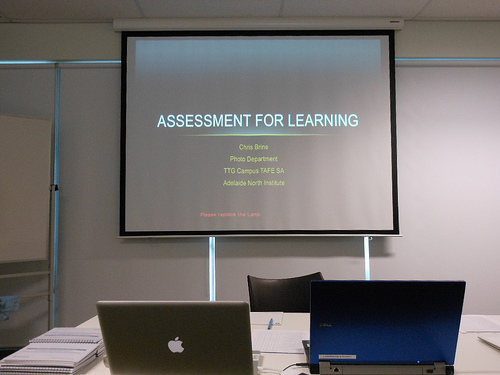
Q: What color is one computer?
A: Blue.